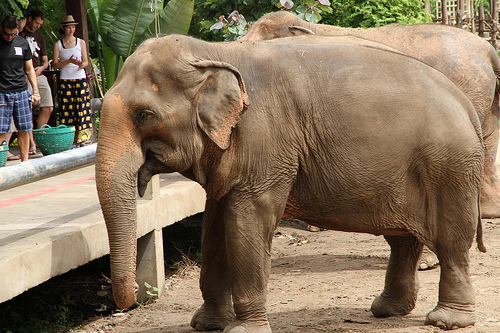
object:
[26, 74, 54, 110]
shorts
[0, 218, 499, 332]
dirt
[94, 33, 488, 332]
elephant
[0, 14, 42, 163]
man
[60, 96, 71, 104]
specks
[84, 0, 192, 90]
plant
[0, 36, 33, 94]
t-shirt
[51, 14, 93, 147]
girl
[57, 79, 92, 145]
skirt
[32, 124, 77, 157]
basket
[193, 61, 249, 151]
ear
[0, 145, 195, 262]
floor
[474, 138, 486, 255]
tail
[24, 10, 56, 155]
man